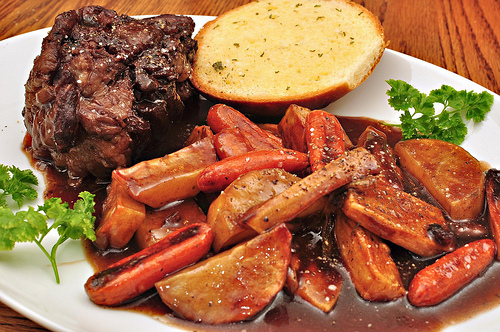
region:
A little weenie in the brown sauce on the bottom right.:
[402, 237, 498, 306]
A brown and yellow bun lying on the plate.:
[186, 1, 388, 119]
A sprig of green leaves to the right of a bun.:
[386, 78, 494, 145]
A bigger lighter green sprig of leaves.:
[1, 164, 96, 282]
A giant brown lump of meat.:
[24, 4, 198, 186]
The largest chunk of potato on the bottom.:
[151, 223, 296, 320]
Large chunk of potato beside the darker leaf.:
[395, 133, 487, 220]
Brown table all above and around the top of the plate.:
[1, 0, 498, 92]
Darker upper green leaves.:
[384, 78, 493, 145]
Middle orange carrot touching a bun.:
[207, 101, 282, 149]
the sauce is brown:
[119, 111, 416, 329]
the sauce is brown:
[199, 175, 397, 312]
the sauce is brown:
[283, 201, 426, 328]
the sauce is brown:
[238, 207, 390, 296]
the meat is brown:
[13, 3, 252, 225]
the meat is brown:
[16, 18, 177, 175]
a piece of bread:
[196, 2, 383, 97]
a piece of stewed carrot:
[90, 234, 200, 299]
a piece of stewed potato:
[161, 227, 293, 316]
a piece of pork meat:
[31, 5, 181, 160]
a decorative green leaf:
[389, 79, 483, 136]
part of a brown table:
[401, 9, 496, 51]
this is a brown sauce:
[298, 311, 404, 330]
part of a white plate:
[0, 47, 25, 111]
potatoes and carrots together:
[116, 129, 493, 318]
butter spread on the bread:
[208, 12, 345, 84]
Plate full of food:
[29, 6, 474, 321]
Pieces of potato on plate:
[185, 151, 489, 294]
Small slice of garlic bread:
[185, 6, 403, 108]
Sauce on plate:
[292, 305, 338, 327]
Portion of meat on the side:
[23, 5, 213, 195]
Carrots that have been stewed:
[201, 116, 393, 323]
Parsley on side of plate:
[4, 150, 97, 308]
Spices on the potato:
[190, 264, 252, 324]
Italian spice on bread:
[195, 51, 245, 83]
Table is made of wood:
[428, 23, 498, 88]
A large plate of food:
[0, 2, 495, 321]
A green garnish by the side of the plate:
[0, 163, 92, 285]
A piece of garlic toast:
[196, 0, 376, 110]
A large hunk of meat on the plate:
[15, 0, 189, 172]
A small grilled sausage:
[86, 222, 211, 302]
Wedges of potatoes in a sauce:
[299, 137, 481, 294]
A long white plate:
[1, 17, 497, 329]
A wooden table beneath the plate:
[1, 0, 497, 89]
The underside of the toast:
[209, 89, 349, 109]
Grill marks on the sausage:
[83, 219, 198, 284]